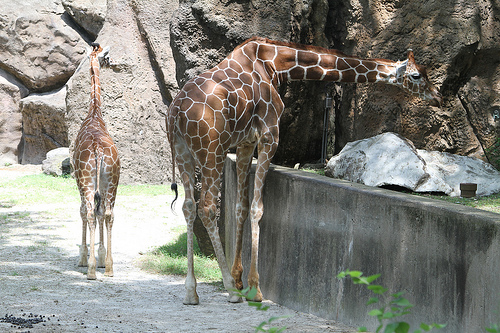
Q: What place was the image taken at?
A: It was taken at the pen.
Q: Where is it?
A: This is at the pen.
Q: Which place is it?
A: It is a pen.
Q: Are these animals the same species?
A: Yes, all the animals are giraffes.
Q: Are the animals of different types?
A: No, all the animals are giraffes.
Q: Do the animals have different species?
A: No, all the animals are giraffes.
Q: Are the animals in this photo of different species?
A: No, all the animals are giraffes.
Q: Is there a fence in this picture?
A: No, there are no fences.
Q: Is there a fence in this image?
A: No, there are no fences.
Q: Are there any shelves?
A: No, there are no shelves.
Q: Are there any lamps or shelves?
A: No, there are no shelves or lamps.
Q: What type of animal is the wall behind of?
A: The wall is behind the giraffe.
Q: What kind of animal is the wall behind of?
A: The wall is behind the giraffe.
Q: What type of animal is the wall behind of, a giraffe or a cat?
A: The wall is behind a giraffe.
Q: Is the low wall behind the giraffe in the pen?
A: Yes, the wall is behind the giraffe.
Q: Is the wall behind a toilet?
A: No, the wall is behind the giraffe.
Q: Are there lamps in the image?
A: No, there are no lamps.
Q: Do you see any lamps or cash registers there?
A: No, there are no lamps or cash registers.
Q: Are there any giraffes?
A: Yes, there is a giraffe.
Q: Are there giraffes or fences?
A: Yes, there is a giraffe.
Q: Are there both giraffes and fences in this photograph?
A: No, there is a giraffe but no fences.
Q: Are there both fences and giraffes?
A: No, there is a giraffe but no fences.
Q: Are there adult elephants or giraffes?
A: Yes, there is an adult giraffe.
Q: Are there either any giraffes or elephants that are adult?
A: Yes, the giraffe is adult.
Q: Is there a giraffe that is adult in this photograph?
A: Yes, there is an adult giraffe.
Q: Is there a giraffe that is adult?
A: Yes, there is a giraffe that is adult.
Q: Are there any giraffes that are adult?
A: Yes, there is a giraffe that is adult.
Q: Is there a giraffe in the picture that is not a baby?
A: Yes, there is a adult giraffe.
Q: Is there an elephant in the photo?
A: No, there are no elephants.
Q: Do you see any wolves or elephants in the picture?
A: No, there are no elephants or wolves.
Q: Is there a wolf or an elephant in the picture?
A: No, there are no elephants or wolves.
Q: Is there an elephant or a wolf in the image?
A: No, there are no elephants or wolves.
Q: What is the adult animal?
A: The animal is a giraffe.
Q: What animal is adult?
A: The animal is a giraffe.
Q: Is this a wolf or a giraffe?
A: This is a giraffe.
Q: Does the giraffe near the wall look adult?
A: Yes, the giraffe is adult.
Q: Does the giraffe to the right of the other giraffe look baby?
A: No, the giraffe is adult.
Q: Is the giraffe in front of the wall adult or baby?
A: The giraffe is adult.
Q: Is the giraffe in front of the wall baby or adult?
A: The giraffe is adult.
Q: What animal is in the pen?
A: The giraffe is in the pen.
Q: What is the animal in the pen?
A: The animal is a giraffe.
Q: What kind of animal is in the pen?
A: The animal is a giraffe.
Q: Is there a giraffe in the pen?
A: Yes, there is a giraffe in the pen.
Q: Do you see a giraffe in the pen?
A: Yes, there is a giraffe in the pen.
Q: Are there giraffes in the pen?
A: Yes, there is a giraffe in the pen.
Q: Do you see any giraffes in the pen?
A: Yes, there is a giraffe in the pen.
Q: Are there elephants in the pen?
A: No, there is a giraffe in the pen.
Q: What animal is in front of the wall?
A: The giraffe is in front of the wall.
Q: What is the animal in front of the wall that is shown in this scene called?
A: The animal is a giraffe.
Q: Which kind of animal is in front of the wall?
A: The animal is a giraffe.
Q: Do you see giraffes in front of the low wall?
A: Yes, there is a giraffe in front of the wall.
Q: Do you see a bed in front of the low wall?
A: No, there is a giraffe in front of the wall.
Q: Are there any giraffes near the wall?
A: Yes, there is a giraffe near the wall.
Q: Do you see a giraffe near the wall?
A: Yes, there is a giraffe near the wall.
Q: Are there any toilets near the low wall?
A: No, there is a giraffe near the wall.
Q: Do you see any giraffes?
A: Yes, there is a giraffe.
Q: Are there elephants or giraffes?
A: Yes, there is a giraffe.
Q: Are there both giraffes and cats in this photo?
A: No, there is a giraffe but no cats.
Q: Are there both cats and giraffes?
A: No, there is a giraffe but no cats.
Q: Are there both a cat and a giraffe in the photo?
A: No, there is a giraffe but no cats.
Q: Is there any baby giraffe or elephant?
A: Yes, there is a baby giraffe.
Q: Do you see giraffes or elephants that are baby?
A: Yes, the giraffe is a baby.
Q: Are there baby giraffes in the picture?
A: Yes, there is a baby giraffe.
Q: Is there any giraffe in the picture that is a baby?
A: Yes, there is a giraffe that is a baby.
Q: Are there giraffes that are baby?
A: Yes, there is a giraffe that is a baby.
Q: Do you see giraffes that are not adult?
A: Yes, there is an baby giraffe.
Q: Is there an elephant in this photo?
A: No, there are no elephants.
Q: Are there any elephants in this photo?
A: No, there are no elephants.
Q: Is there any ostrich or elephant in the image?
A: No, there are no elephants or ostriches.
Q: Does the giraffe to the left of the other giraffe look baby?
A: Yes, the giraffe is a baby.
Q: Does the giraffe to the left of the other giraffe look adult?
A: No, the giraffe is a baby.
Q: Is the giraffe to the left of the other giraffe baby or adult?
A: The giraffe is a baby.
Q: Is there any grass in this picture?
A: Yes, there is grass.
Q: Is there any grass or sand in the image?
A: Yes, there is grass.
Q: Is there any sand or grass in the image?
A: Yes, there is grass.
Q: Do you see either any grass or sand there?
A: Yes, there is grass.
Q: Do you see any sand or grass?
A: Yes, there is grass.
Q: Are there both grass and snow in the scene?
A: No, there is grass but no snow.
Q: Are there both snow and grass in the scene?
A: No, there is grass but no snow.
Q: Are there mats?
A: No, there are no mats.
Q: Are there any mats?
A: No, there are no mats.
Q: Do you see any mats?
A: No, there are no mats.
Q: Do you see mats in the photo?
A: No, there are no mats.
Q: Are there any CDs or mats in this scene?
A: No, there are no mats or cds.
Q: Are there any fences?
A: No, there are no fences.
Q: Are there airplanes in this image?
A: No, there are no airplanes.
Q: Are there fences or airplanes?
A: No, there are no airplanes or fences.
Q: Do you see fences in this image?
A: No, there are no fences.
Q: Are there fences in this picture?
A: No, there are no fences.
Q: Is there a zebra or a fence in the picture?
A: No, there are no fences or zebras.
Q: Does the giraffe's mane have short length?
A: Yes, the mane is short.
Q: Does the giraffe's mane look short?
A: Yes, the mane is short.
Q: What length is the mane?
A: The mane is short.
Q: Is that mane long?
A: No, the mane is short.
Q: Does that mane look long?
A: No, the mane is short.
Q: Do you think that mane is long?
A: No, the mane is short.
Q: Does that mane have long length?
A: No, the mane is short.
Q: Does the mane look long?
A: No, the mane is short.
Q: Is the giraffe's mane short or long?
A: The mane is short.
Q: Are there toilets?
A: No, there are no toilets.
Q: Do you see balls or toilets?
A: No, there are no toilets or balls.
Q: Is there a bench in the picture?
A: No, there are no benches.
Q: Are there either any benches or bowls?
A: No, there are no benches or bowls.